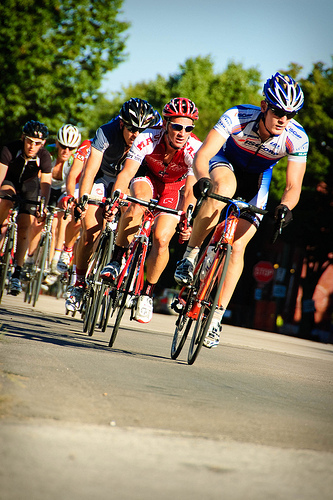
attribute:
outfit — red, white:
[124, 127, 202, 219]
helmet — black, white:
[115, 97, 156, 130]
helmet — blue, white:
[261, 69, 306, 114]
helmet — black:
[19, 119, 52, 138]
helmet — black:
[114, 92, 158, 127]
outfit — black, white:
[84, 99, 165, 145]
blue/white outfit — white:
[205, 100, 307, 224]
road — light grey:
[4, 289, 331, 497]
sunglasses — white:
[167, 121, 194, 131]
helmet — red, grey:
[260, 72, 305, 108]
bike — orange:
[170, 180, 288, 364]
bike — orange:
[108, 189, 192, 347]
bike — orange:
[1, 191, 44, 300]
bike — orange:
[24, 195, 70, 307]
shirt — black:
[0, 138, 54, 183]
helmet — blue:
[260, 68, 307, 120]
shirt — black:
[215, 101, 310, 190]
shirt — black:
[90, 113, 153, 189]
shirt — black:
[1, 138, 52, 215]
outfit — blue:
[200, 103, 310, 230]